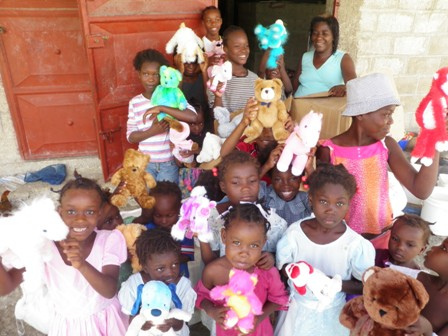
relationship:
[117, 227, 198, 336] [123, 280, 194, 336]
child holding stuffed animal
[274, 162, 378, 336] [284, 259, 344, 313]
child holding stuffed animal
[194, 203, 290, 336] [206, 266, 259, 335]
child holding bear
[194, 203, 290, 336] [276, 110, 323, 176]
child holding stuffed animal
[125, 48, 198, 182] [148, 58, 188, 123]
child hugging bear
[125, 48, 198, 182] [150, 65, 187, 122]
child hugging animal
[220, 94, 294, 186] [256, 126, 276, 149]
kid on h head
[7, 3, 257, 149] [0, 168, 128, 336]
door behind child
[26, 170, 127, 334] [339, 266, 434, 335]
child with stuffed animal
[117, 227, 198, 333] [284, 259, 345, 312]
child with stuffed animal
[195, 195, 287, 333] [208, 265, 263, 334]
child with stuffed animal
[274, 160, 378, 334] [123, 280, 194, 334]
child with stuffed animal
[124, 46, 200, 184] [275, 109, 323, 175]
child with stuffed animal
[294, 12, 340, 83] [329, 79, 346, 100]
woman has hand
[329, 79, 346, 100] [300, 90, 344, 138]
hand in box